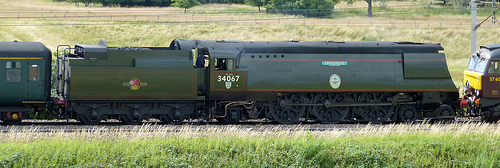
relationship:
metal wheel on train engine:
[271, 97, 455, 123] [196, 36, 459, 121]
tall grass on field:
[3, 125, 498, 167] [1, 118, 498, 166]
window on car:
[2, 58, 26, 82] [0, 38, 58, 121]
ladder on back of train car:
[55, 45, 65, 97] [51, 44, 469, 127]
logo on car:
[113, 65, 155, 107] [55, 42, 455, 114]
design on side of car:
[321, 72, 344, 90] [54, 35, 460, 128]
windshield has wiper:
[466, 55, 486, 72] [476, 57, 483, 62]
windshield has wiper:
[466, 55, 486, 72] [470, 55, 474, 60]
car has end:
[56, 37, 203, 105] [53, 39, 90, 103]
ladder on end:
[55, 45, 65, 97] [53, 39, 90, 103]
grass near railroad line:
[0, 132, 498, 166] [1, 112, 495, 129]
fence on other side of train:
[2, 2, 498, 31] [1, 35, 498, 129]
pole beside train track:
[468, 1, 478, 53] [2, 125, 499, 130]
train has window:
[0, 39, 500, 125] [4, 61, 17, 79]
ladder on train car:
[55, 45, 65, 97] [54, 40, 206, 105]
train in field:
[0, 39, 500, 125] [10, 120, 484, 161]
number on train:
[213, 63, 253, 88] [0, 39, 500, 125]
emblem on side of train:
[119, 75, 146, 92] [14, 41, 485, 111]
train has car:
[0, 39, 500, 125] [0, 43, 50, 110]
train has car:
[0, 39, 500, 125] [61, 42, 453, 107]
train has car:
[0, 39, 500, 125] [457, 47, 484, 103]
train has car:
[14, 41, 485, 111] [461, 35, 484, 102]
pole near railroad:
[436, 40, 496, 119] [7, 39, 484, 123]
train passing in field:
[14, 41, 485, 111] [10, 125, 484, 165]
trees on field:
[254, 0, 341, 20] [0, 0, 485, 40]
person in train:
[215, 58, 232, 71] [3, 31, 496, 117]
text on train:
[319, 59, 354, 68] [1, 35, 498, 129]